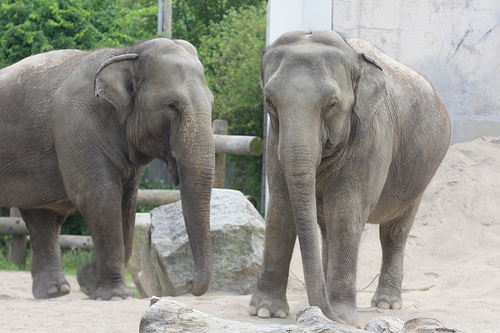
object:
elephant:
[0, 37, 216, 302]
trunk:
[172, 124, 217, 296]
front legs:
[75, 181, 137, 295]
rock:
[137, 187, 265, 297]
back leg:
[16, 203, 73, 280]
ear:
[93, 53, 137, 126]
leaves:
[13, 27, 51, 49]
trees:
[0, 0, 266, 138]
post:
[157, 0, 174, 38]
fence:
[0, 119, 263, 272]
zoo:
[0, 0, 499, 333]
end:
[189, 275, 211, 295]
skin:
[0, 56, 95, 208]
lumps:
[130, 37, 199, 60]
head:
[92, 37, 216, 185]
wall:
[264, 0, 500, 140]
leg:
[261, 168, 297, 295]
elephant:
[246, 29, 451, 325]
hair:
[119, 36, 170, 47]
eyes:
[161, 100, 180, 114]